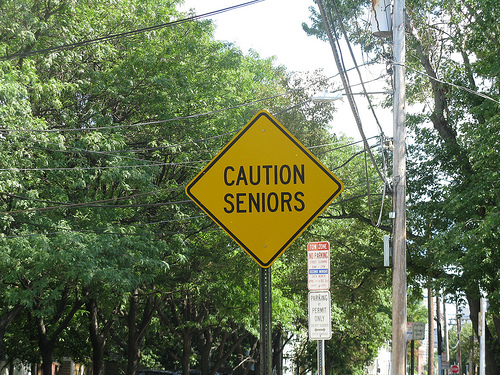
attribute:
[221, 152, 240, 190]
letter — written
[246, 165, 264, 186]
letter — t, written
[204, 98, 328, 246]
sign — yellow, diamond, black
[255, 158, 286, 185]
letter — i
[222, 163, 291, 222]
letter — e, o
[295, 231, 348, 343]
sign — green, white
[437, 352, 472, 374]
sign — distant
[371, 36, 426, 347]
pole — wood, green, wooden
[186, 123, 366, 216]
letting — black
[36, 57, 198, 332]
tree — green, behind, distant, present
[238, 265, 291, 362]
pole — iron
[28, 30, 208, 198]
wires — running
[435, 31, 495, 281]
trees — tall